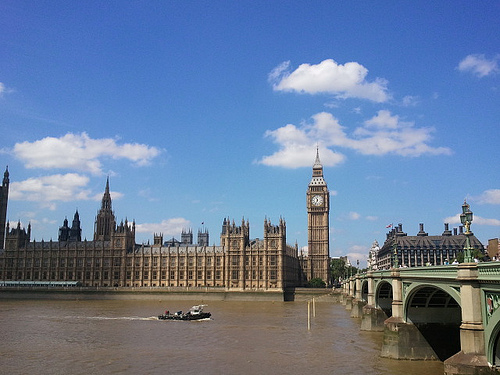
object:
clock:
[312, 194, 323, 206]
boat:
[157, 304, 212, 321]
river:
[0, 297, 500, 375]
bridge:
[340, 261, 499, 375]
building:
[0, 141, 331, 290]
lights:
[460, 198, 473, 224]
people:
[398, 259, 460, 269]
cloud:
[0, 52, 499, 271]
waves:
[64, 315, 157, 321]